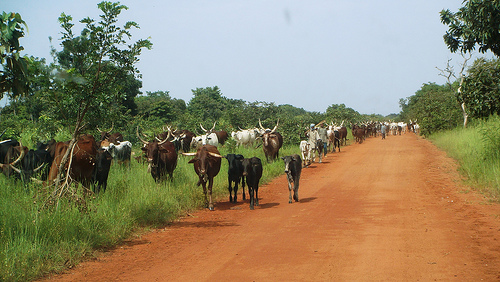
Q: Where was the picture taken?
A: It was taken at the road.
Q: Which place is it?
A: It is a road.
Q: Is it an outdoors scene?
A: Yes, it is outdoors.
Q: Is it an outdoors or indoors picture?
A: It is outdoors.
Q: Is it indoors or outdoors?
A: It is outdoors.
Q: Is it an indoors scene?
A: No, it is outdoors.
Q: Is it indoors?
A: No, it is outdoors.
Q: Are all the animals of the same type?
A: No, there are both cows and bulls.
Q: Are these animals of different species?
A: Yes, they are cows and bulls.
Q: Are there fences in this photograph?
A: No, there are no fences.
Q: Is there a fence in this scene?
A: No, there are no fences.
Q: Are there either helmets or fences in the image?
A: No, there are no fences or helmets.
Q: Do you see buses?
A: No, there are no buses.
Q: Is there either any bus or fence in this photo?
A: No, there are no buses or fences.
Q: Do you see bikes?
A: No, there are no bikes.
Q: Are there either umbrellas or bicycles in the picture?
A: No, there are no bicycles or umbrellas.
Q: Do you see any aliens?
A: No, there are no aliens.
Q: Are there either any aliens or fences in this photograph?
A: No, there are no aliens or fences.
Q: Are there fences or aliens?
A: No, there are no aliens or fences.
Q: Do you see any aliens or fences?
A: No, there are no aliens or fences.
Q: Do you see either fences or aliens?
A: No, there are no aliens or fences.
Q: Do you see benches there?
A: No, there are no benches.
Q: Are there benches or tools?
A: No, there are no benches or tools.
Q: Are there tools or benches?
A: No, there are no benches or tools.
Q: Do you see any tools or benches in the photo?
A: No, there are no benches or tools.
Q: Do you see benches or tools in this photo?
A: No, there are no benches or tools.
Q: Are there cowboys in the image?
A: No, there are no cowboys.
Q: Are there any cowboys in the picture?
A: No, there are no cowboys.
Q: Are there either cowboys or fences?
A: No, there are no cowboys or fences.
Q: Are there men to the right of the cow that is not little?
A: Yes, there is a man to the right of the cow.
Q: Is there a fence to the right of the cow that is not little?
A: No, there is a man to the right of the cow.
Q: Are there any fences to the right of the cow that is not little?
A: No, there is a man to the right of the cow.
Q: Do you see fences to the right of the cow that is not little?
A: No, there is a man to the right of the cow.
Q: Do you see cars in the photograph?
A: No, there are no cars.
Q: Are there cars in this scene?
A: No, there are no cars.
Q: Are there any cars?
A: No, there are no cars.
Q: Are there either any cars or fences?
A: No, there are no cars or fences.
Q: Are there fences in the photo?
A: No, there are no fences.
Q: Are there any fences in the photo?
A: No, there are no fences.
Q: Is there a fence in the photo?
A: No, there are no fences.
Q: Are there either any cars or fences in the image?
A: No, there are no fences or cars.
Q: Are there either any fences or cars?
A: No, there are no fences or cars.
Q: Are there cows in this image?
A: Yes, there is a cow.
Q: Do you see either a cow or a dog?
A: Yes, there is a cow.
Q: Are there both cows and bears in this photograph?
A: No, there is a cow but no bears.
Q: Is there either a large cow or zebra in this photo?
A: Yes, there is a large cow.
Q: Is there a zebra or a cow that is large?
A: Yes, the cow is large.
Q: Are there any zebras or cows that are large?
A: Yes, the cow is large.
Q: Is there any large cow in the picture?
A: Yes, there is a large cow.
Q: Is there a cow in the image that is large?
A: Yes, there is a cow that is large.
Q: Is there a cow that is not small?
A: Yes, there is a large cow.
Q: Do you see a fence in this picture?
A: No, there are no fences.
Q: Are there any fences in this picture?
A: No, there are no fences.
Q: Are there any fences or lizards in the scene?
A: No, there are no fences or lizards.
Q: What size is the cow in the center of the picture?
A: The cow is large.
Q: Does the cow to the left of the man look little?
A: No, the cow is large.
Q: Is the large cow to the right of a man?
A: No, the cow is to the left of a man.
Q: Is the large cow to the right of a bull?
A: Yes, the cow is to the right of a bull.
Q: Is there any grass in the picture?
A: Yes, there is grass.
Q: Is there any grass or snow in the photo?
A: Yes, there is grass.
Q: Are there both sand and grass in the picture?
A: No, there is grass but no sand.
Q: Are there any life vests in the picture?
A: No, there are no life vests.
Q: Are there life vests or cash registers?
A: No, there are no life vests or cash registers.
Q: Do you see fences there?
A: No, there are no fences.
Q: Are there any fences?
A: No, there are no fences.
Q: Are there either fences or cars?
A: No, there are no fences or cars.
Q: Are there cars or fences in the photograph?
A: No, there are no fences or cars.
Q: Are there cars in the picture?
A: No, there are no cars.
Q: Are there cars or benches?
A: No, there are no cars or benches.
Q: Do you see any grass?
A: Yes, there is grass.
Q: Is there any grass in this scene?
A: Yes, there is grass.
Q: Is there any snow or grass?
A: Yes, there is grass.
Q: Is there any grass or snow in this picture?
A: Yes, there is grass.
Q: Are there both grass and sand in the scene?
A: No, there is grass but no sand.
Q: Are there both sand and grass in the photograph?
A: No, there is grass but no sand.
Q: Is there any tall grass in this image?
A: Yes, there is tall grass.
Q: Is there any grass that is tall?
A: Yes, there is grass that is tall.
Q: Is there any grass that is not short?
A: Yes, there is tall grass.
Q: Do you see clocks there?
A: No, there are no clocks.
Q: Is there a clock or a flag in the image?
A: No, there are no clocks or flags.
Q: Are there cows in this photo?
A: Yes, there is a cow.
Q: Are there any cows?
A: Yes, there is a cow.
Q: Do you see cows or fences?
A: Yes, there is a cow.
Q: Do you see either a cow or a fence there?
A: Yes, there is a cow.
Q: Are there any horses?
A: No, there are no horses.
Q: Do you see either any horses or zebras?
A: No, there are no horses or zebras.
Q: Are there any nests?
A: No, there are no nests.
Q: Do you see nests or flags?
A: No, there are no nests or flags.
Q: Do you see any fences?
A: No, there are no fences.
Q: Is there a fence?
A: No, there are no fences.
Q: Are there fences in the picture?
A: No, there are no fences.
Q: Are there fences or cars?
A: No, there are no fences or cars.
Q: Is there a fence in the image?
A: No, there are no fences.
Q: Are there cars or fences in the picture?
A: No, there are no fences or cars.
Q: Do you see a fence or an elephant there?
A: No, there are no fences or elephants.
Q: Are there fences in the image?
A: No, there are no fences.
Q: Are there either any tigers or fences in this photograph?
A: No, there are no fences or tigers.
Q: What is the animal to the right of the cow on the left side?
A: The animal is a bull.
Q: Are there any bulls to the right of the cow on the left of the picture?
A: Yes, there is a bull to the right of the cow.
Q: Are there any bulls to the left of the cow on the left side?
A: No, the bull is to the right of the cow.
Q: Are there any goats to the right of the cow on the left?
A: No, there is a bull to the right of the cow.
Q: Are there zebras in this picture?
A: No, there are no zebras.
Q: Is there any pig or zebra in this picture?
A: No, there are no zebras or pigs.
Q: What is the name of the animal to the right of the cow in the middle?
A: The animal is a bull.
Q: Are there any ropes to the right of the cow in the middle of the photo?
A: No, there is a bull to the right of the cow.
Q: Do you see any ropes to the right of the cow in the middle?
A: No, there is a bull to the right of the cow.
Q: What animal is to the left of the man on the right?
A: The animal is a bull.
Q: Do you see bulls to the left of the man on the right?
A: Yes, there is a bull to the left of the man.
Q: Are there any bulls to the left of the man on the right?
A: Yes, there is a bull to the left of the man.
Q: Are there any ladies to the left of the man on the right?
A: No, there is a bull to the left of the man.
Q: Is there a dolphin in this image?
A: No, there are no dolphins.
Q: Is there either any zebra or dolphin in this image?
A: No, there are no dolphins or zebras.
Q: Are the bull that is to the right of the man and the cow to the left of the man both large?
A: Yes, both the bull and the cow are large.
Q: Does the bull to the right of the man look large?
A: Yes, the bull is large.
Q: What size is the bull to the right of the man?
A: The bull is large.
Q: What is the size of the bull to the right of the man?
A: The bull is large.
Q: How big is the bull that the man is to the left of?
A: The bull is large.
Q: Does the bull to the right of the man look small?
A: No, the bull is large.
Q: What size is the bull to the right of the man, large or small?
A: The bull is large.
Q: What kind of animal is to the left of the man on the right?
A: The animal is a bull.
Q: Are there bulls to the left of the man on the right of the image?
A: Yes, there is a bull to the left of the man.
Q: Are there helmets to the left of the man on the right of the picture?
A: No, there is a bull to the left of the man.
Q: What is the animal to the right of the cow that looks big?
A: The animal is a bull.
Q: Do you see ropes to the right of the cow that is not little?
A: No, there is a bull to the right of the cow.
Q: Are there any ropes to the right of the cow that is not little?
A: No, there is a bull to the right of the cow.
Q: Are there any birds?
A: No, there are no birds.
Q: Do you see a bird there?
A: No, there are no birds.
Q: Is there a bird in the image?
A: No, there are no birds.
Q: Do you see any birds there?
A: No, there are no birds.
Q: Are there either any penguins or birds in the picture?
A: No, there are no birds or penguins.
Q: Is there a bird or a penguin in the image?
A: No, there are no birds or penguins.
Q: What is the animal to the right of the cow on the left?
A: The animal is a bull.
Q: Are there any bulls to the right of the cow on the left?
A: Yes, there is a bull to the right of the cow.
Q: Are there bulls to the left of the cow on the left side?
A: No, the bull is to the right of the cow.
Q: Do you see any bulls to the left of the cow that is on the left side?
A: No, the bull is to the right of the cow.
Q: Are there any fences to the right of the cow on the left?
A: No, there is a bull to the right of the cow.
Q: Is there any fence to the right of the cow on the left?
A: No, there is a bull to the right of the cow.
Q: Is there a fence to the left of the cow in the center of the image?
A: No, there is a bull to the left of the cow.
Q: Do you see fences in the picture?
A: No, there are no fences.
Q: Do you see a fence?
A: No, there are no fences.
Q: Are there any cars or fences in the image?
A: No, there are no fences or cars.